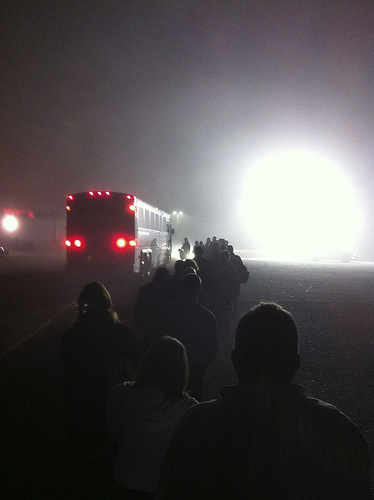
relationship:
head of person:
[233, 301, 300, 388] [166, 301, 368, 499]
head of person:
[141, 336, 189, 387] [104, 336, 198, 497]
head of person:
[77, 283, 119, 327] [62, 282, 126, 414]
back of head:
[153, 265, 169, 285] [152, 267, 173, 289]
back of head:
[229, 302, 301, 386] [233, 301, 300, 388]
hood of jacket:
[121, 384, 192, 416] [113, 382, 199, 498]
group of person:
[50, 237, 370, 499] [166, 301, 368, 499]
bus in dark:
[65, 191, 172, 275] [0, 3, 373, 500]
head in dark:
[233, 301, 300, 388] [0, 3, 373, 500]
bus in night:
[65, 191, 172, 275] [2, 2, 372, 275]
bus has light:
[65, 191, 172, 275] [119, 238, 126, 248]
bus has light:
[65, 191, 172, 275] [73, 238, 82, 248]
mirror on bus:
[169, 228, 178, 236] [65, 191, 172, 275]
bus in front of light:
[65, 191, 172, 275] [226, 137, 373, 267]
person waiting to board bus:
[166, 301, 368, 499] [65, 191, 172, 275]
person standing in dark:
[166, 301, 368, 499] [0, 3, 373, 500]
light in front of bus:
[226, 137, 373, 267] [65, 191, 172, 275]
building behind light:
[212, 138, 374, 267] [226, 137, 373, 267]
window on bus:
[139, 208, 144, 228] [65, 191, 172, 275]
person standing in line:
[166, 301, 368, 499] [133, 234, 247, 375]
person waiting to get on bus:
[166, 301, 368, 499] [65, 191, 172, 275]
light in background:
[226, 137, 373, 267] [0, 0, 372, 305]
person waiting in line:
[166, 301, 368, 499] [133, 234, 247, 375]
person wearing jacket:
[104, 336, 198, 497] [113, 382, 199, 498]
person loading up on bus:
[179, 236, 193, 261] [65, 191, 172, 275]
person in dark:
[62, 282, 126, 414] [0, 3, 373, 500]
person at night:
[62, 282, 126, 414] [2, 2, 372, 275]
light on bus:
[119, 238, 126, 248] [65, 191, 172, 275]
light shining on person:
[226, 137, 373, 267] [179, 236, 193, 261]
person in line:
[62, 282, 126, 414] [133, 234, 247, 375]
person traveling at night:
[62, 282, 126, 414] [2, 2, 372, 275]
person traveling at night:
[104, 336, 198, 497] [2, 2, 372, 275]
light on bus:
[125, 193, 134, 202] [65, 191, 172, 275]